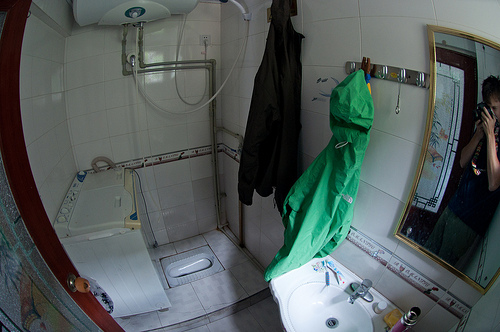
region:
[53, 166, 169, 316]
a white washing unit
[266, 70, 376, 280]
a light green coat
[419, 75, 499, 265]
person in mirror reflection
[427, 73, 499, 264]
a person holding a camera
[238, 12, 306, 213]
a black coat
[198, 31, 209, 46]
a white electrical socket with plug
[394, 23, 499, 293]
a gold framed mirror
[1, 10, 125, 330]
a wood frame glass door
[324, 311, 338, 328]
a drain in a sink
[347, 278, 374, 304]
a silver faucet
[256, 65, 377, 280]
Green coat hanging on the wall.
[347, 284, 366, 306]
Faucet to the sink.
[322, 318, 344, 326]
Drain hole in the sink.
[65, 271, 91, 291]
The door knob on the door.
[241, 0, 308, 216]
Black coat hanging on the wall.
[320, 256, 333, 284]
Toothbrush on the sink.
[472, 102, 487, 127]
Camera in the man's hand.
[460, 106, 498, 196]
The arms of the guy.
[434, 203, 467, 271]
The pants the man is wearing.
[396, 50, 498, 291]
The mirror on the wall.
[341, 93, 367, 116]
the jacket is green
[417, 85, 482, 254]
reflection in the mirror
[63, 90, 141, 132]
tile on the wall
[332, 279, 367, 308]
nozzle of the sink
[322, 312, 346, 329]
drain of the sink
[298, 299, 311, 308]
the sink is white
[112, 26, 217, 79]
pipe on the wall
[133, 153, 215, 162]
pattern on hte tile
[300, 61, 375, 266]
a jacket hanging in a bathroom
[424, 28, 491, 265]
a large mirror in a bathroom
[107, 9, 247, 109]
wires hanging in a bathroom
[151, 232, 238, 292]
a small squat toilet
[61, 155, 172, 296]
a large white square machine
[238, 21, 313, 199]
a large black coat hanging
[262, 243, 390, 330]
a sink that has nothing in it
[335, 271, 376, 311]
a silver colored water faucet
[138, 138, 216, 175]
the boarder that circles the entire bathroom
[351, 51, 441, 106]
a coat rack attached to the wall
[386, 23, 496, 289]
man in mirror taking photo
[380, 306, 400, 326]
bar of yellow soap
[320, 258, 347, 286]
a tube of toothpaste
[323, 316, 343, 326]
drain hole of a bathroom sink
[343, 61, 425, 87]
silver clothing hooks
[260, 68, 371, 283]
green rain jacket hanging from wall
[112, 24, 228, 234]
silver pipes leading to ceiling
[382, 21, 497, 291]
a mirror with a gold frame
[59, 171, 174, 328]
a small washer and dryer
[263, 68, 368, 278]
light green jacket hangs on stainless hook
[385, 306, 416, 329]
tall pink bottle with stainless lid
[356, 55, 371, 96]
orange rusted pliers with blue and orange handle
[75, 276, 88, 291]
orange cover on brass door knob on red door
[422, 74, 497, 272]
man with brown hair holds black camera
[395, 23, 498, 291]
bathroom mirror in frame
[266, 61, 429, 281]
green jacket hanging from hook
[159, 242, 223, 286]
oblong squat toilet in floor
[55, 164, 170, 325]
two appliances side by side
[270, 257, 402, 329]
top view of bathroom sink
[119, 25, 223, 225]
metal plumbing pipes against tile wall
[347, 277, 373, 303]
top of metal faucet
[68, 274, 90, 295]
reflection on door knob